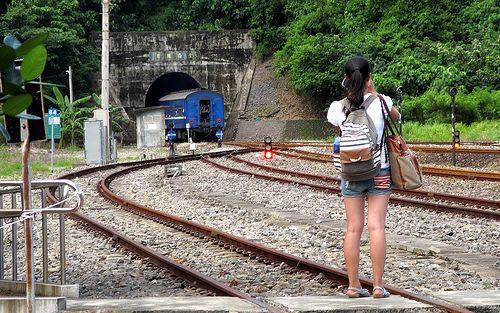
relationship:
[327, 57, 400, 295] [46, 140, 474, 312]
girl on track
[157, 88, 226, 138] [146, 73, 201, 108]
train going thru tunnel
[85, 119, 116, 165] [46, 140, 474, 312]
box beside track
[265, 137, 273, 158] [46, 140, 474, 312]
light on track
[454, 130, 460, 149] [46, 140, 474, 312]
light on track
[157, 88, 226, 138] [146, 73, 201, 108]
train coming out of tunnel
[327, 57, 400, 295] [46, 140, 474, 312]
girl standing on track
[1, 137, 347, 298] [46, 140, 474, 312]
rocks between track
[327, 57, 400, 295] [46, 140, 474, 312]
girl standing near track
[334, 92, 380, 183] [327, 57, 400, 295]
backpack worn by girl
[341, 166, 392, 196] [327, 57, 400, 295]
shorts worn by girl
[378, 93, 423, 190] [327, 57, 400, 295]
bag carried by girl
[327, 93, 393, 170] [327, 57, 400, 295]
shirt worn by girl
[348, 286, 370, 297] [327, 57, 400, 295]
sandal worn by girl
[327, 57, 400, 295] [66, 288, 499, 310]
girl standing on walkway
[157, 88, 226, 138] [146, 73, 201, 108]
train going in tunnel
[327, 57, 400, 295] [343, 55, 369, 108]
girl with ponytail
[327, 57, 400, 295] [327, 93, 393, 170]
girl in shirt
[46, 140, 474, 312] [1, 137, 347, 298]
track and rocks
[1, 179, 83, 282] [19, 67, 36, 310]
rail around tree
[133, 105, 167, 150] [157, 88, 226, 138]
shack next to train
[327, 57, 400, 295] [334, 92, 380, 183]
girl wearing backpack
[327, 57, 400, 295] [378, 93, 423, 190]
girl holding bag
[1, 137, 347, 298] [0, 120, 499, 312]
rocks on ground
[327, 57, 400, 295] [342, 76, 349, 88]
girl using phone